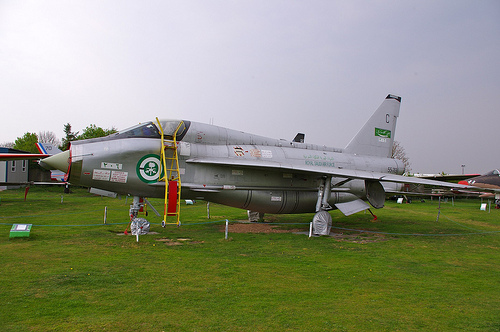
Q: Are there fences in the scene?
A: No, there are no fences.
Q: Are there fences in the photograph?
A: No, there are no fences.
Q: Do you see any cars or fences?
A: No, there are no fences or cars.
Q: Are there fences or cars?
A: No, there are no fences or cars.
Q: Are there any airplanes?
A: Yes, there is an airplane.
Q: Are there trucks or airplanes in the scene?
A: Yes, there is an airplane.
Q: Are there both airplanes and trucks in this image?
A: No, there is an airplane but no trucks.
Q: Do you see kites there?
A: No, there are no kites.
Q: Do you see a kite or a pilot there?
A: No, there are no kites or pilots.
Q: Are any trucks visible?
A: No, there are no trucks.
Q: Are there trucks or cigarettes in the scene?
A: No, there are no trucks or cigarettes.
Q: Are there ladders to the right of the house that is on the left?
A: Yes, there is a ladder to the right of the house.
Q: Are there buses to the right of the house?
A: No, there is a ladder to the right of the house.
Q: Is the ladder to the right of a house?
A: Yes, the ladder is to the right of a house.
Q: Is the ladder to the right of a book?
A: No, the ladder is to the right of a house.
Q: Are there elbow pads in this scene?
A: No, there are no elbow pads.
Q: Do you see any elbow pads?
A: No, there are no elbow pads.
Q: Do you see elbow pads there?
A: No, there are no elbow pads.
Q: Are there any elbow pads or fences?
A: No, there are no elbow pads or fences.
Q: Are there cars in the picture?
A: No, there are no cars.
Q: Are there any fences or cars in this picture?
A: No, there are no cars or fences.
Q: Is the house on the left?
A: Yes, the house is on the left of the image.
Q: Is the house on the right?
A: No, the house is on the left of the image.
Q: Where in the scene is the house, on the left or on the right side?
A: The house is on the left of the image.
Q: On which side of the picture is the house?
A: The house is on the left of the image.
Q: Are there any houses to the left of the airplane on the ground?
A: Yes, there is a house to the left of the plane.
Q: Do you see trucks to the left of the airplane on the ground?
A: No, there is a house to the left of the plane.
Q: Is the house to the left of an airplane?
A: Yes, the house is to the left of an airplane.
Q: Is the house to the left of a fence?
A: No, the house is to the left of an airplane.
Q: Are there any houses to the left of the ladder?
A: Yes, there is a house to the left of the ladder.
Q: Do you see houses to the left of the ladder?
A: Yes, there is a house to the left of the ladder.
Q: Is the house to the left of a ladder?
A: Yes, the house is to the left of a ladder.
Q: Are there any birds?
A: No, there are no birds.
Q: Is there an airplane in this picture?
A: Yes, there is an airplane.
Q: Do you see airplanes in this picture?
A: Yes, there is an airplane.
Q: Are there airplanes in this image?
A: Yes, there is an airplane.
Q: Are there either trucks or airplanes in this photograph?
A: Yes, there is an airplane.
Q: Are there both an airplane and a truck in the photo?
A: No, there is an airplane but no trucks.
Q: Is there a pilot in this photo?
A: No, there are no pilots.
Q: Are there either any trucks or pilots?
A: No, there are no pilots or trucks.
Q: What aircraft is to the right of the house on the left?
A: The aircraft is an airplane.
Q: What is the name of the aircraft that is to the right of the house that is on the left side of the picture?
A: The aircraft is an airplane.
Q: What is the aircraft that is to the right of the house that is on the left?
A: The aircraft is an airplane.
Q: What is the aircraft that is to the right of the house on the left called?
A: The aircraft is an airplane.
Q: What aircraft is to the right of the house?
A: The aircraft is an airplane.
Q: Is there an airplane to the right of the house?
A: Yes, there is an airplane to the right of the house.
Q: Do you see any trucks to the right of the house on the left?
A: No, there is an airplane to the right of the house.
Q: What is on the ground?
A: The plane is on the ground.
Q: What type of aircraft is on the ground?
A: The aircraft is an airplane.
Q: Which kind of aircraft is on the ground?
A: The aircraft is an airplane.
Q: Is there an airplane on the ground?
A: Yes, there is an airplane on the ground.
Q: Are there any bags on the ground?
A: No, there is an airplane on the ground.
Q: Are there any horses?
A: No, there are no horses.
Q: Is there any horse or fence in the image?
A: No, there are no horses or fences.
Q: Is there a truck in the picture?
A: No, there are no trucks.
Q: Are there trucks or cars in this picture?
A: No, there are no trucks or cars.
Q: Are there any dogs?
A: No, there are no dogs.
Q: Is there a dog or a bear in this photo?
A: No, there are no dogs or bears.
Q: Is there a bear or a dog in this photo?
A: No, there are no dogs or bears.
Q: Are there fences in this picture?
A: No, there are no fences.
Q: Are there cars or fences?
A: No, there are no fences or cars.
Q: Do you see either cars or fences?
A: No, there are no fences or cars.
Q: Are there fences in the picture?
A: No, there are no fences.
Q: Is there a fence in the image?
A: No, there are no fences.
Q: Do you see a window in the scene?
A: Yes, there is a window.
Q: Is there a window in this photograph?
A: Yes, there is a window.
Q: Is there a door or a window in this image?
A: Yes, there is a window.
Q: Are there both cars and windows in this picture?
A: No, there is a window but no cars.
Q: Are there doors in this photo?
A: No, there are no doors.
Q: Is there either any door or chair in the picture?
A: No, there are no doors or chairs.